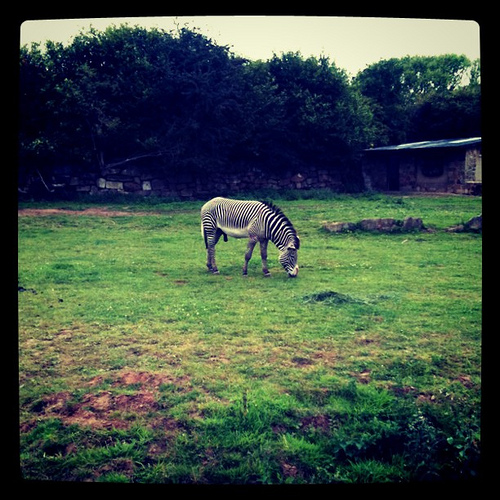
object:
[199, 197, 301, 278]
zebra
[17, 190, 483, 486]
grass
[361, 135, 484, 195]
building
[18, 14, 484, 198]
background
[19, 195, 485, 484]
field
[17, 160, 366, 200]
fence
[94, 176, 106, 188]
stone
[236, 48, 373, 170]
trees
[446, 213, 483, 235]
rocks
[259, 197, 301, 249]
mane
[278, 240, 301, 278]
head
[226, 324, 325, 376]
patches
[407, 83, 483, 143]
tree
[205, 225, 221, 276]
legs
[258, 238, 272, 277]
front leg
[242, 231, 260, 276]
front legs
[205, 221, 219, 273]
rear legs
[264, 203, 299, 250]
neck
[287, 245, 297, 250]
ear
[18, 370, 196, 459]
dirt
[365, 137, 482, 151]
roof